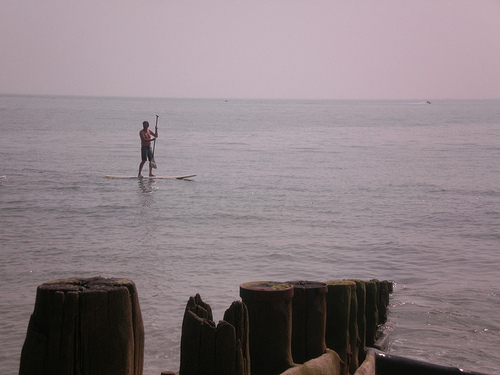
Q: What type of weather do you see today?
A: It is foggy.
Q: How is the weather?
A: It is foggy.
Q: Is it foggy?
A: Yes, it is foggy.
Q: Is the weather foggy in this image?
A: Yes, it is foggy.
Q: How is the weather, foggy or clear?
A: It is foggy.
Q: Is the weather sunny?
A: No, it is foggy.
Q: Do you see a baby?
A: No, there are no babies.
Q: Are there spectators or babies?
A: No, there are no babies or spectators.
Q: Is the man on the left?
A: Yes, the man is on the left of the image.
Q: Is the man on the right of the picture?
A: No, the man is on the left of the image.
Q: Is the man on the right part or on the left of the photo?
A: The man is on the left of the image.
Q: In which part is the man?
A: The man is on the left of the image.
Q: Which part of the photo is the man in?
A: The man is on the left of the image.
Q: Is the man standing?
A: Yes, the man is standing.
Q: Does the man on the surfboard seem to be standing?
A: Yes, the man is standing.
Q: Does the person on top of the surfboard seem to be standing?
A: Yes, the man is standing.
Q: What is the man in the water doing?
A: The man is standing.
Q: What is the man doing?
A: The man is standing.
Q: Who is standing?
A: The man is standing.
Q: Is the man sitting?
A: No, the man is standing.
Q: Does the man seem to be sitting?
A: No, the man is standing.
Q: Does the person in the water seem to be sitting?
A: No, the man is standing.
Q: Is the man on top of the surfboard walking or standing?
A: The man is standing.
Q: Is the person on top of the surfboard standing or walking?
A: The man is standing.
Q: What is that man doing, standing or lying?
A: The man is standing.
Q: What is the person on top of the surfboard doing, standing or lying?
A: The man is standing.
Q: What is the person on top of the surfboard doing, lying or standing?
A: The man is standing.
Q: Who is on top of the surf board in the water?
A: The man is on top of the surf board.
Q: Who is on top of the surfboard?
A: The man is on top of the surf board.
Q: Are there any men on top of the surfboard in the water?
A: Yes, there is a man on top of the surfboard.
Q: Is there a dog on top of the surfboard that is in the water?
A: No, there is a man on top of the surfboard.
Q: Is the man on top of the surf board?
A: Yes, the man is on top of the surf board.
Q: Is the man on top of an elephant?
A: No, the man is on top of the surf board.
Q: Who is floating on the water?
A: The man is floating on the water.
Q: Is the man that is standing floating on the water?
A: Yes, the man is floating on the water.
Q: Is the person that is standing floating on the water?
A: Yes, the man is floating on the water.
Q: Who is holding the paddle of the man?
A: The man is holding the oar.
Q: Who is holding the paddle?
A: The man is holding the oar.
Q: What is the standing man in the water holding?
A: The man is holding the oar.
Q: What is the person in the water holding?
A: The man is holding the oar.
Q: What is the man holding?
A: The man is holding the oar.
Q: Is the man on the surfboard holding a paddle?
A: Yes, the man is holding a paddle.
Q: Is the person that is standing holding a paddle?
A: Yes, the man is holding a paddle.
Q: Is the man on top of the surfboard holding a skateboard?
A: No, the man is holding a paddle.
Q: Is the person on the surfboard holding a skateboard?
A: No, the man is holding a paddle.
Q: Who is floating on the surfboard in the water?
A: The man is floating on the surfboard.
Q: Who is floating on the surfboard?
A: The man is floating on the surfboard.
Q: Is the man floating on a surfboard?
A: Yes, the man is floating on a surfboard.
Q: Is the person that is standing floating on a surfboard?
A: Yes, the man is floating on a surfboard.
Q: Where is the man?
A: The man is in the water.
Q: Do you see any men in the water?
A: Yes, there is a man in the water.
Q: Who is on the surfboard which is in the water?
A: The man is on the surfboard.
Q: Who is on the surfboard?
A: The man is on the surfboard.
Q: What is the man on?
A: The man is on the surfboard.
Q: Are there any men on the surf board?
A: Yes, there is a man on the surf board.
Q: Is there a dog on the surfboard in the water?
A: No, there is a man on the surfboard.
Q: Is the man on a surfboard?
A: Yes, the man is on a surfboard.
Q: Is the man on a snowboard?
A: No, the man is on a surfboard.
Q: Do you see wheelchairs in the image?
A: No, there are no wheelchairs.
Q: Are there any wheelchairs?
A: No, there are no wheelchairs.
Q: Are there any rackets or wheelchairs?
A: No, there are no wheelchairs or rackets.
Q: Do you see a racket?
A: No, there are no rackets.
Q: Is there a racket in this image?
A: No, there are no rackets.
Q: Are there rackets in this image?
A: No, there are no rackets.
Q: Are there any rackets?
A: No, there are no rackets.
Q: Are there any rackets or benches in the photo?
A: No, there are no rackets or benches.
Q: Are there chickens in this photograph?
A: No, there are no chickens.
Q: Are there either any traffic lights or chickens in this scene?
A: No, there are no chickens or traffic lights.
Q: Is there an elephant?
A: No, there are no elephants.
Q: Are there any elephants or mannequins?
A: No, there are no elephants or mannequins.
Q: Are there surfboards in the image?
A: Yes, there is a surfboard.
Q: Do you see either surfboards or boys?
A: Yes, there is a surfboard.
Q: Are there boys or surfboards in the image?
A: Yes, there is a surfboard.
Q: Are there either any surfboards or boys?
A: Yes, there is a surfboard.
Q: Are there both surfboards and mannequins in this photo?
A: No, there is a surfboard but no mannequins.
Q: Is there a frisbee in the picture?
A: No, there are no frisbees.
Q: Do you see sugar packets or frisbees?
A: No, there are no frisbees or sugar packets.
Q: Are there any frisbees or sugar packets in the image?
A: No, there are no frisbees or sugar packets.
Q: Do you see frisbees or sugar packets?
A: No, there are no frisbees or sugar packets.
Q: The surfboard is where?
A: The surfboard is in the water.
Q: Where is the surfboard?
A: The surfboard is in the water.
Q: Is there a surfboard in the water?
A: Yes, there is a surfboard in the water.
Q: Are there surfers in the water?
A: No, there is a surfboard in the water.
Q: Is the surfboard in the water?
A: Yes, the surfboard is in the water.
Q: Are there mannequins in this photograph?
A: No, there are no mannequins.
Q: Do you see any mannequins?
A: No, there are no mannequins.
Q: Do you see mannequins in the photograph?
A: No, there are no mannequins.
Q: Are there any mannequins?
A: No, there are no mannequins.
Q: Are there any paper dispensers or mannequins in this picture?
A: No, there are no mannequins or paper dispensers.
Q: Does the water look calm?
A: Yes, the water is calm.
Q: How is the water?
A: The water is calm.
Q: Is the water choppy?
A: No, the water is calm.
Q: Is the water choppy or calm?
A: The water is calm.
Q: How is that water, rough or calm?
A: The water is calm.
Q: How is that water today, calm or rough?
A: The water is calm.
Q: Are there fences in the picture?
A: No, there are no fences.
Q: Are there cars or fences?
A: No, there are no fences or cars.